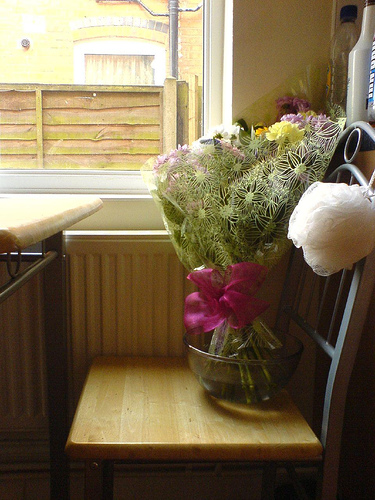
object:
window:
[83, 53, 154, 85]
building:
[0, 0, 204, 88]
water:
[192, 375, 298, 407]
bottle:
[345, 0, 374, 126]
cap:
[337, 3, 358, 22]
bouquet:
[140, 58, 348, 403]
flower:
[280, 113, 306, 130]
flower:
[214, 129, 232, 141]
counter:
[0, 193, 103, 248]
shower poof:
[286, 169, 375, 280]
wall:
[0, 75, 203, 168]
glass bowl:
[181, 325, 305, 402]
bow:
[183, 262, 271, 334]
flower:
[276, 96, 311, 123]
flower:
[315, 119, 341, 139]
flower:
[221, 140, 245, 160]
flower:
[192, 163, 212, 179]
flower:
[265, 120, 305, 145]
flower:
[255, 127, 268, 135]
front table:
[0, 193, 101, 252]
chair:
[63, 121, 375, 497]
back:
[279, 271, 374, 444]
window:
[0, 0, 231, 237]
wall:
[68, 236, 185, 359]